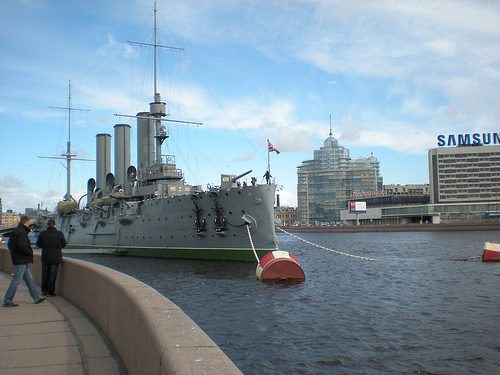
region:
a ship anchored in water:
[38, 2, 282, 275]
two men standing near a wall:
[2, 212, 69, 307]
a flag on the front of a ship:
[247, 135, 287, 201]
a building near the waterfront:
[418, 123, 498, 253]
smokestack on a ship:
[86, 123, 117, 224]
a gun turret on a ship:
[210, 160, 258, 202]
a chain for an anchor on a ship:
[234, 211, 266, 271]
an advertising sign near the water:
[341, 195, 374, 237]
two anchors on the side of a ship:
[182, 195, 236, 240]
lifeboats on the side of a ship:
[53, 182, 128, 217]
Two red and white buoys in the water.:
[246, 251, 498, 283]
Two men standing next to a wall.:
[0, 215, 72, 310]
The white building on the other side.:
[298, 110, 388, 229]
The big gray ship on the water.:
[59, 25, 288, 252]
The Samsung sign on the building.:
[431, 130, 498, 207]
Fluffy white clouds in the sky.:
[221, 98, 323, 138]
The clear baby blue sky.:
[216, 53, 303, 84]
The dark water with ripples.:
[248, 286, 498, 373]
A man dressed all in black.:
[34, 218, 69, 300]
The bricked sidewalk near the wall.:
[0, 311, 120, 372]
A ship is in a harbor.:
[0, 0, 295, 275]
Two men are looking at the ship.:
[0, 210, 70, 310]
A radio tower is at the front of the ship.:
[110, 0, 205, 175]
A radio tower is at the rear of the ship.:
[30, 70, 96, 215]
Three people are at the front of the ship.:
[225, 161, 285, 197]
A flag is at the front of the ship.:
[260, 136, 285, 182]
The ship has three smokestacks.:
[75, 100, 165, 201]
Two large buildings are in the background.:
[276, 105, 498, 235]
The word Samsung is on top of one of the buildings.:
[432, 125, 497, 150]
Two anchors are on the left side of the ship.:
[185, 185, 230, 240]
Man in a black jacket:
[8, 213, 53, 302]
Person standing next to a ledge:
[34, 217, 79, 310]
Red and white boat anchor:
[241, 226, 313, 296]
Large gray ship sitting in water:
[32, 126, 313, 293]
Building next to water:
[289, 111, 401, 246]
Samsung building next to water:
[418, 128, 499, 236]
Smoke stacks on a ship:
[91, 116, 241, 258]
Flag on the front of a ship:
[255, 132, 317, 237]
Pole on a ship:
[43, 63, 126, 218]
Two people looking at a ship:
[4, 211, 98, 331]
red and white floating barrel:
[245, 245, 310, 289]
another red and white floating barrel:
[479, 237, 499, 263]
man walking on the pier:
[3, 214, 43, 306]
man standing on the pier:
[36, 216, 68, 298]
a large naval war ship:
[29, 5, 281, 260]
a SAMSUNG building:
[422, 126, 499, 206]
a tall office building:
[294, 113, 384, 225]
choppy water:
[0, 217, 498, 374]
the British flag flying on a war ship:
[264, 137, 281, 187]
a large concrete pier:
[1, 247, 243, 374]